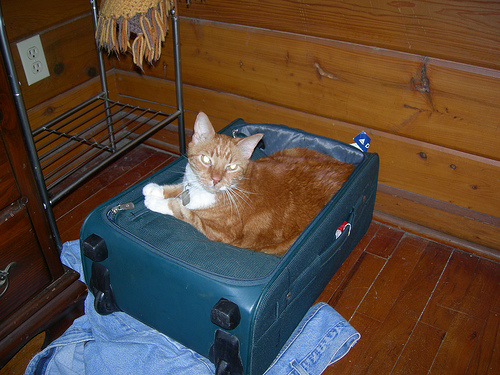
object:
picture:
[3, 4, 494, 374]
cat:
[143, 111, 357, 252]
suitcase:
[78, 116, 379, 374]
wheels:
[90, 282, 120, 315]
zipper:
[105, 200, 128, 220]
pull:
[111, 201, 136, 212]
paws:
[144, 197, 172, 216]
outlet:
[14, 34, 51, 88]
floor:
[363, 262, 491, 368]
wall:
[391, 36, 487, 213]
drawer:
[0, 216, 48, 326]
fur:
[249, 163, 312, 227]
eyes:
[199, 152, 213, 168]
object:
[90, 0, 174, 67]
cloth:
[70, 315, 164, 369]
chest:
[188, 183, 209, 210]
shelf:
[30, 90, 180, 186]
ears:
[190, 110, 216, 144]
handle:
[308, 208, 357, 272]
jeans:
[26, 313, 212, 374]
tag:
[350, 130, 371, 152]